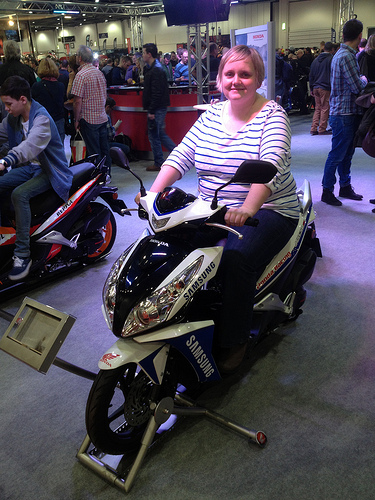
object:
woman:
[133, 44, 301, 371]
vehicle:
[83, 146, 323, 457]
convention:
[1, 2, 374, 500]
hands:
[133, 191, 249, 230]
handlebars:
[217, 207, 259, 227]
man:
[318, 18, 369, 207]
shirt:
[329, 44, 367, 117]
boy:
[0, 73, 75, 282]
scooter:
[2, 152, 118, 303]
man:
[141, 42, 178, 172]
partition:
[108, 81, 220, 160]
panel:
[102, 229, 225, 339]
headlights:
[102, 241, 204, 338]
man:
[69, 44, 111, 183]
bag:
[68, 129, 88, 165]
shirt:
[69, 61, 111, 124]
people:
[2, 18, 375, 373]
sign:
[229, 22, 274, 105]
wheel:
[85, 354, 178, 457]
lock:
[75, 395, 207, 494]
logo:
[185, 336, 216, 379]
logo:
[183, 261, 217, 301]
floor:
[0, 112, 373, 498]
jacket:
[143, 59, 170, 110]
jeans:
[145, 109, 174, 167]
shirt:
[160, 97, 301, 220]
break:
[119, 206, 243, 240]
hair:
[215, 45, 266, 96]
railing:
[15, 1, 212, 109]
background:
[2, 0, 373, 172]